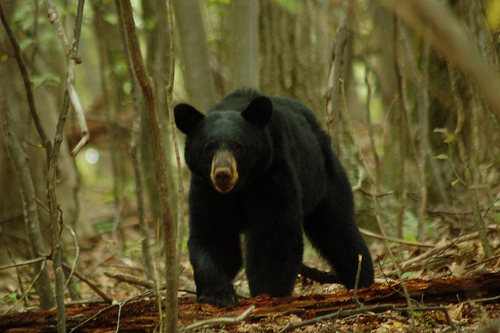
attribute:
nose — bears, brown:
[209, 163, 234, 185]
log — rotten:
[3, 268, 498, 325]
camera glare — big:
[68, 130, 110, 182]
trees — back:
[8, 0, 496, 315]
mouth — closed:
[211, 168, 240, 189]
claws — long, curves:
[187, 288, 247, 315]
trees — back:
[196, 27, 419, 122]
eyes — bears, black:
[184, 128, 266, 165]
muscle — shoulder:
[212, 77, 278, 108]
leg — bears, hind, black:
[308, 216, 376, 281]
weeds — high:
[0, 80, 194, 331]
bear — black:
[168, 88, 378, 310]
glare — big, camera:
[77, 140, 111, 168]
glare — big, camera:
[79, 134, 106, 169]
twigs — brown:
[46, 234, 486, 323]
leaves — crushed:
[347, 291, 432, 325]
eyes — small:
[221, 138, 257, 159]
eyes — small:
[204, 145, 217, 155]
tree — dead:
[107, 287, 266, 331]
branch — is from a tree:
[45, 65, 154, 236]